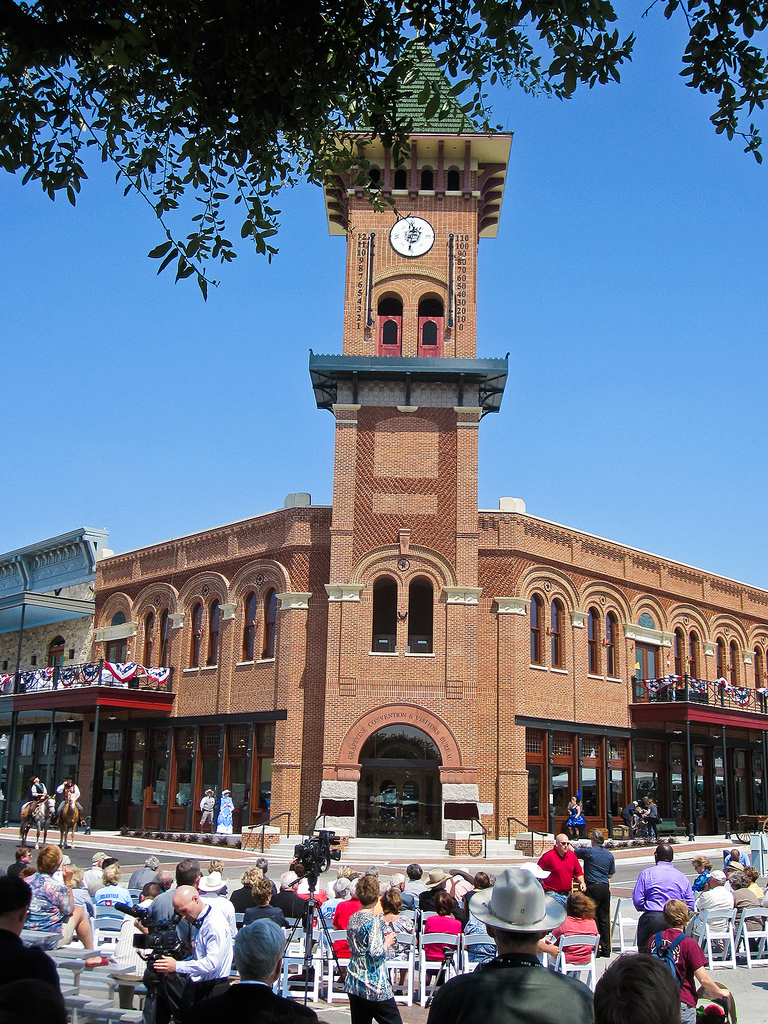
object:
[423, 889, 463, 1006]
person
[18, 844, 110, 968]
woman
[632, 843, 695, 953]
man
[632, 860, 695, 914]
shirt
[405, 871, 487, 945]
puppy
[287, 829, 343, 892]
camera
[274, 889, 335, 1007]
tripod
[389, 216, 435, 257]
clock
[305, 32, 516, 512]
tower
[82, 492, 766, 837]
building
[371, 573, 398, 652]
building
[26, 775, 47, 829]
person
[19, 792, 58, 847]
horse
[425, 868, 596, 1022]
man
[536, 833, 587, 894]
bald man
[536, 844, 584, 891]
red shirt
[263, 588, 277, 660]
window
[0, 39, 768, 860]
brick building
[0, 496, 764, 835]
building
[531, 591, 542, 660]
window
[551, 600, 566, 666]
window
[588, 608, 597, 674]
window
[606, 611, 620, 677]
window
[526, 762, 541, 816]
window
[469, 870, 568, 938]
brimmed hat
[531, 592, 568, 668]
window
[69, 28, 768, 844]
building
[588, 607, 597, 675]
window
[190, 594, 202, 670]
window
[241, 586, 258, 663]
window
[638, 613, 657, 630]
window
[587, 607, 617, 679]
window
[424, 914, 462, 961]
shirt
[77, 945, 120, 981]
shoes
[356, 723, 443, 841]
doorway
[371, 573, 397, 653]
window